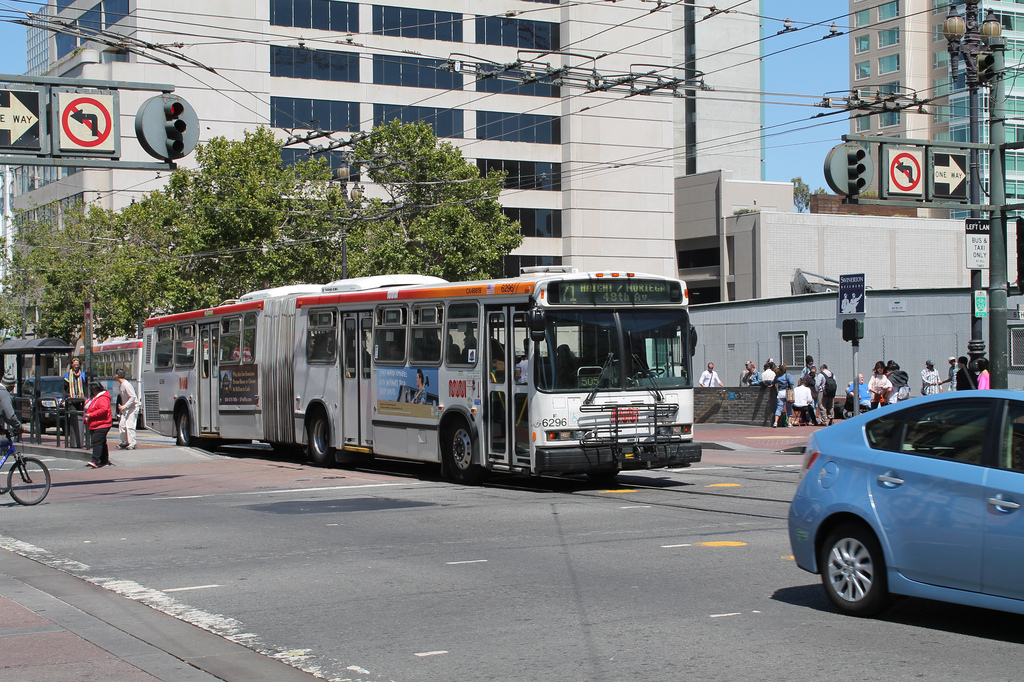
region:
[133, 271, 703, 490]
a long white public service bus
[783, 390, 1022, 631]
a light blue car in street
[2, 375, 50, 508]
a person on bicycle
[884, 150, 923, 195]
a no left turn sign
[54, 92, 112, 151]
a no left turn sign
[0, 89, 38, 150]
a one way sign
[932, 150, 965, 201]
a one way sign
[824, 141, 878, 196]
an electric traffic signal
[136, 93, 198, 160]
an electric traffic signal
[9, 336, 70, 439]
a public transportation shelter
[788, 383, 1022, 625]
Powder blue Toyota Prius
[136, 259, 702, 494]
Double long bus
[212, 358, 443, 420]
Ads on side of double bus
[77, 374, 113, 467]
Short lady wearing red jacket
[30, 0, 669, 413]
Office building with dark windows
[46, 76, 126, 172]
No left turn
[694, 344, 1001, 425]
Big group of people standing on street corner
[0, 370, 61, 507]
Person on a bicycle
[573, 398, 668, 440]
Bike rack on front of bus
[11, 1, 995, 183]
Many utility wires over intersection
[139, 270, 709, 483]
A bus on a street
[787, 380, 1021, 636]
A blue car on a street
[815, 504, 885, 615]
A tire on a car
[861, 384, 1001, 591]
A door on a car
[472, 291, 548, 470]
Doors on a bus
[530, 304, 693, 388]
Windshield on a bus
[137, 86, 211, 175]
A stoplight in a city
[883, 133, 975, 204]
Street signs on a pole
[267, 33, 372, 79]
Windows on a building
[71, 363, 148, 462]
People standing in a street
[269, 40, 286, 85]
a window on a building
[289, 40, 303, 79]
a window on a building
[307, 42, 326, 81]
a window on a building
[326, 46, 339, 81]
a window on a building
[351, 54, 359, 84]
a window on a building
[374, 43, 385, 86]
a window on a building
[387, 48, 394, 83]
a window on a building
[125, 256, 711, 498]
A long white city bus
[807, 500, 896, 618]
A black round car tire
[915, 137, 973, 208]
White arrow on a black sign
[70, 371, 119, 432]
Person wearing a red coat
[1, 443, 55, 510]
A black bicycle wheel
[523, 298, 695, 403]
Front windows on a bus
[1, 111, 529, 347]
Green leaves on the trees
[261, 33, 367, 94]
Windows on side of a building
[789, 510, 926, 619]
tire on a car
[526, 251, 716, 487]
bus on a street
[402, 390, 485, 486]
tire on a bus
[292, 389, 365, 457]
tire on a bus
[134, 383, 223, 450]
tire on a bus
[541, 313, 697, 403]
window on a bus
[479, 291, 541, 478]
door on a bus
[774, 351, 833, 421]
a person on the sidewalk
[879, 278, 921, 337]
a person on the sidewalk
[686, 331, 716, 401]
a person on the sidewalk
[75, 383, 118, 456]
a person in a red jacket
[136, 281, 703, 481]
a large white bus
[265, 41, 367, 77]
windows on the building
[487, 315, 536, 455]
the door on the bus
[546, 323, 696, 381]
the windshield on the bus